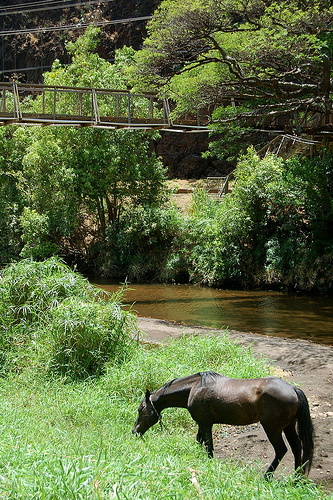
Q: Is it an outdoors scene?
A: Yes, it is outdoors.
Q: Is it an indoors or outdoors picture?
A: It is outdoors.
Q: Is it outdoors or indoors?
A: It is outdoors.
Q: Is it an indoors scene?
A: No, it is outdoors.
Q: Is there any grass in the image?
A: Yes, there is grass.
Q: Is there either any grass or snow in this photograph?
A: Yes, there is grass.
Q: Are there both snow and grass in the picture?
A: No, there is grass but no snow.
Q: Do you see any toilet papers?
A: No, there are no toilet papers.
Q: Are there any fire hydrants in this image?
A: No, there are no fire hydrants.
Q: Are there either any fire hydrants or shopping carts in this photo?
A: No, there are no fire hydrants or shopping carts.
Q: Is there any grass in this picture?
A: Yes, there is grass.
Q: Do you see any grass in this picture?
A: Yes, there is grass.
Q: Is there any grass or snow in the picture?
A: Yes, there is grass.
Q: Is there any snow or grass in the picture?
A: Yes, there is grass.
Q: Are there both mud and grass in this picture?
A: No, there is grass but no mud.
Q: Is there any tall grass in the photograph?
A: Yes, there is tall grass.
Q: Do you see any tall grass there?
A: Yes, there is tall grass.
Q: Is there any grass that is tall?
A: Yes, there is grass that is tall.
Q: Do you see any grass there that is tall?
A: Yes, there is grass that is tall.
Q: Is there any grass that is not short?
A: Yes, there is tall grass.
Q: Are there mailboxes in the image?
A: No, there are no mailboxes.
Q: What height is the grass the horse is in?
A: The grass is tall.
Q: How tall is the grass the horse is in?
A: The grass is tall.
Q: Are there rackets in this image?
A: No, there are no rackets.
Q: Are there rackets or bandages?
A: No, there are no rackets or bandages.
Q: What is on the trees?
A: The leaves are on the trees.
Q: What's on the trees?
A: The leaves are on the trees.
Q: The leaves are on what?
A: The leaves are on the trees.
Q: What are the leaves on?
A: The leaves are on the trees.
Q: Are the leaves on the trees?
A: Yes, the leaves are on the trees.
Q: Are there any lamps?
A: No, there are no lamps.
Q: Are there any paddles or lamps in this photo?
A: No, there are no lamps or paddles.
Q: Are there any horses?
A: Yes, there is a horse.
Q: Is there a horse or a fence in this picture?
A: Yes, there is a horse.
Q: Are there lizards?
A: No, there are no lizards.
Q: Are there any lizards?
A: No, there are no lizards.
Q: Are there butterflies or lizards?
A: No, there are no lizards or butterflies.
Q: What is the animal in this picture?
A: The animal is a horse.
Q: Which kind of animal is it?
A: The animal is a horse.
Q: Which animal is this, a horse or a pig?
A: This is a horse.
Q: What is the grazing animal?
A: The animal is a horse.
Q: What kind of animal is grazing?
A: The animal is a horse.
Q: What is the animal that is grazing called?
A: The animal is a horse.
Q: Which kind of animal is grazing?
A: The animal is a horse.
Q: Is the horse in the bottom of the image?
A: Yes, the horse is in the bottom of the image.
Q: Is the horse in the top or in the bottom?
A: The horse is in the bottom of the image.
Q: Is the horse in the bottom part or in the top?
A: The horse is in the bottom of the image.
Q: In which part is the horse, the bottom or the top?
A: The horse is in the bottom of the image.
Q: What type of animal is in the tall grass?
A: The animal is a horse.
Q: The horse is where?
A: The horse is in the grass.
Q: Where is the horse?
A: The horse is in the grass.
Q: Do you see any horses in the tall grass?
A: Yes, there is a horse in the grass.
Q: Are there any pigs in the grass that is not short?
A: No, there is a horse in the grass.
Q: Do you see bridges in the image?
A: Yes, there is a bridge.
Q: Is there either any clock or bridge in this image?
A: Yes, there is a bridge.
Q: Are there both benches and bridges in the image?
A: No, there is a bridge but no benches.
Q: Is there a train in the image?
A: No, there are no trains.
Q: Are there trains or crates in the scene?
A: No, there are no trains or crates.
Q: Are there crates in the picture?
A: No, there are no crates.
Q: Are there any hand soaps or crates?
A: No, there are no crates or hand soaps.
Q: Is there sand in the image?
A: Yes, there is sand.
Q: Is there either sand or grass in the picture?
A: Yes, there is sand.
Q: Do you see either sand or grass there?
A: Yes, there is sand.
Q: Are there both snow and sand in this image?
A: No, there is sand but no snow.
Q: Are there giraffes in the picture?
A: No, there are no giraffes.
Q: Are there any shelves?
A: No, there are no shelves.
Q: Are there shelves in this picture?
A: No, there are no shelves.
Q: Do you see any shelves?
A: No, there are no shelves.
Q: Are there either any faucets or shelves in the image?
A: No, there are no shelves or faucets.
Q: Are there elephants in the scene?
A: No, there are no elephants.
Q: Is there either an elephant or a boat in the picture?
A: No, there are no elephants or boats.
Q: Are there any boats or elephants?
A: No, there are no elephants or boats.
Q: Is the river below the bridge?
A: Yes, the river is below the bridge.